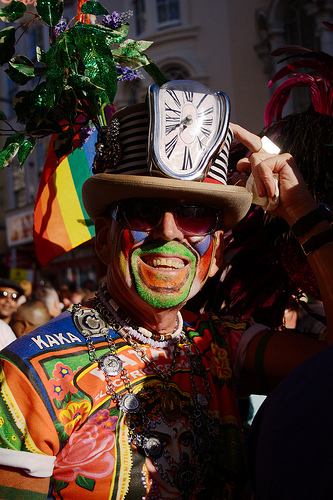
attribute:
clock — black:
[164, 67, 224, 174]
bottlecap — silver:
[74, 309, 114, 335]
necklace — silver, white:
[125, 353, 185, 367]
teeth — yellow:
[146, 260, 182, 270]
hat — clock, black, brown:
[82, 77, 251, 205]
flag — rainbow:
[48, 158, 84, 185]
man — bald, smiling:
[11, 111, 256, 417]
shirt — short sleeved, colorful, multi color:
[14, 335, 226, 488]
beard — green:
[153, 297, 169, 309]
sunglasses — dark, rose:
[127, 199, 203, 231]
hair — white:
[103, 217, 119, 232]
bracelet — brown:
[287, 217, 322, 240]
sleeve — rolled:
[223, 321, 315, 352]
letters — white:
[49, 327, 89, 343]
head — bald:
[114, 201, 132, 208]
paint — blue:
[173, 249, 185, 257]